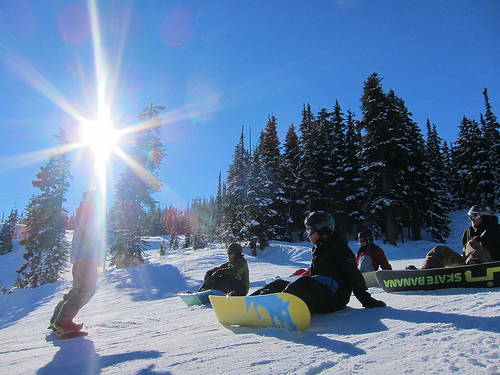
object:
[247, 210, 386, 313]
man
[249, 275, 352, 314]
pants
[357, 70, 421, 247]
tree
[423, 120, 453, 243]
tree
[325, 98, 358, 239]
tree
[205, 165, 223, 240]
tree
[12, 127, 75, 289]
tree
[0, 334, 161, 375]
snow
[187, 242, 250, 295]
people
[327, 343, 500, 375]
snow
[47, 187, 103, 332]
man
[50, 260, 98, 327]
pants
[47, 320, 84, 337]
snowboard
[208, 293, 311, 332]
snowboard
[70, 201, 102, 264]
jacket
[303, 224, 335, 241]
goggles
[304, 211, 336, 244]
head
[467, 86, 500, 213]
tree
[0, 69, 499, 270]
background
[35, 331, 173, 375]
shadow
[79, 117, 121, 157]
sun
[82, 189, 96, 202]
helmet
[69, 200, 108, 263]
coat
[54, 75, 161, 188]
circle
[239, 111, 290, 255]
branches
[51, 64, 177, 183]
glare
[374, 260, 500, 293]
writing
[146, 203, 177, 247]
trees